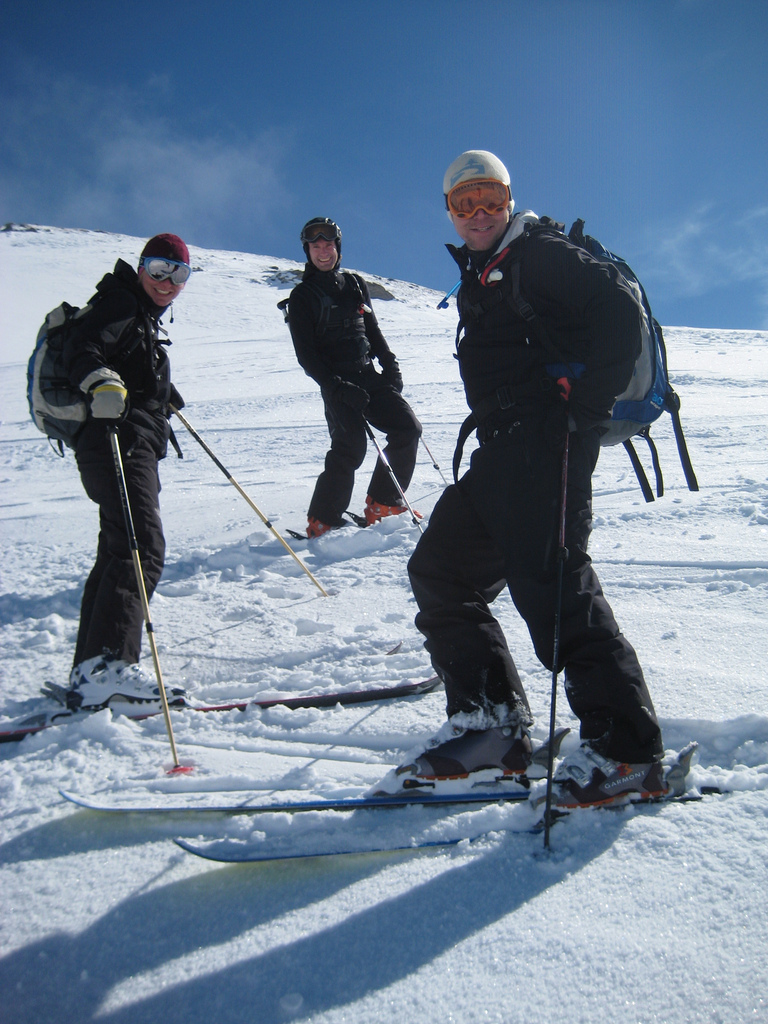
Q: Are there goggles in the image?
A: Yes, there are goggles.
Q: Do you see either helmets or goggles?
A: Yes, there are goggles.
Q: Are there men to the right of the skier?
A: Yes, there is a man to the right of the skier.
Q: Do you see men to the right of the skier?
A: Yes, there is a man to the right of the skier.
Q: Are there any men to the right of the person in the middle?
A: Yes, there is a man to the right of the skier.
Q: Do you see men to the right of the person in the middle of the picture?
A: Yes, there is a man to the right of the skier.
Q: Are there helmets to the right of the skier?
A: No, there is a man to the right of the skier.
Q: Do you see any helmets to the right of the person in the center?
A: No, there is a man to the right of the skier.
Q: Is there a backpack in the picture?
A: Yes, there is a backpack.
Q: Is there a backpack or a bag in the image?
A: Yes, there is a backpack.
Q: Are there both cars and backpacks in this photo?
A: No, there is a backpack but no cars.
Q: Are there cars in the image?
A: No, there are no cars.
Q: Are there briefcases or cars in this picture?
A: No, there are no cars or briefcases.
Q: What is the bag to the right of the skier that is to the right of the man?
A: The bag is a backpack.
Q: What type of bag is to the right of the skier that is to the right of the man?
A: The bag is a backpack.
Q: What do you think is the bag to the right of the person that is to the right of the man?
A: The bag is a backpack.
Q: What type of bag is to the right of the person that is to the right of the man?
A: The bag is a backpack.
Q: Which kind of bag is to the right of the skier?
A: The bag is a backpack.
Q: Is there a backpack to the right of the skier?
A: Yes, there is a backpack to the right of the skier.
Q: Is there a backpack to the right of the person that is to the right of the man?
A: Yes, there is a backpack to the right of the skier.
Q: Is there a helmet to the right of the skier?
A: No, there is a backpack to the right of the skier.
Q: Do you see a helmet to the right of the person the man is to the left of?
A: No, there is a backpack to the right of the skier.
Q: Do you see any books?
A: No, there are no books.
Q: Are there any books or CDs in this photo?
A: No, there are no books or cds.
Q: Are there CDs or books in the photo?
A: No, there are no books or cds.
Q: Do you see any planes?
A: No, there are no planes.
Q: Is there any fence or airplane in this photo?
A: No, there are no airplanes or fences.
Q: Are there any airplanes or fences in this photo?
A: No, there are no airplanes or fences.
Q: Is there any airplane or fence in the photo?
A: No, there are no airplanes or fences.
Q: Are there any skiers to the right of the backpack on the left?
A: Yes, there is a skier to the right of the backpack.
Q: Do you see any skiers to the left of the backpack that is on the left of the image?
A: No, the skier is to the right of the backpack.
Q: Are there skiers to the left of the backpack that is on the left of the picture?
A: No, the skier is to the right of the backpack.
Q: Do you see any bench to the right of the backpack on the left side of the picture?
A: No, there is a skier to the right of the backpack.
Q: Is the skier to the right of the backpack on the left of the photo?
A: Yes, the skier is to the right of the backpack.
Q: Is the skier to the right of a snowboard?
A: No, the skier is to the right of the backpack.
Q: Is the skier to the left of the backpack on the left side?
A: No, the skier is to the right of the backpack.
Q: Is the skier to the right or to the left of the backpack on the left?
A: The skier is to the right of the backpack.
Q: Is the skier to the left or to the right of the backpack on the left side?
A: The skier is to the right of the backpack.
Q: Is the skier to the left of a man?
A: Yes, the skier is to the left of a man.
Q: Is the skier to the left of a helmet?
A: No, the skier is to the left of a man.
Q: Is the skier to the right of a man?
A: No, the skier is to the left of a man.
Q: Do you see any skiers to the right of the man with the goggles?
A: Yes, there is a skier to the right of the man.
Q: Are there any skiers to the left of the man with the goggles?
A: No, the skier is to the right of the man.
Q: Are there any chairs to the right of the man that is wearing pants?
A: No, there is a skier to the right of the man.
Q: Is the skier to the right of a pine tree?
A: No, the skier is to the right of a man.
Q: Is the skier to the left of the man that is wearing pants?
A: No, the skier is to the right of the man.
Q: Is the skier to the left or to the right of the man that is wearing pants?
A: The skier is to the right of the man.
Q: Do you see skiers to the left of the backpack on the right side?
A: Yes, there is a skier to the left of the backpack.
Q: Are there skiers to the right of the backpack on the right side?
A: No, the skier is to the left of the backpack.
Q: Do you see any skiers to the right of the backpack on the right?
A: No, the skier is to the left of the backpack.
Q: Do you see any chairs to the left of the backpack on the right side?
A: No, there is a skier to the left of the backpack.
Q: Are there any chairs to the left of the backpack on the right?
A: No, there is a skier to the left of the backpack.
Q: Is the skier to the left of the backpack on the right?
A: Yes, the skier is to the left of the backpack.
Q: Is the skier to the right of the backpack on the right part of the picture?
A: No, the skier is to the left of the backpack.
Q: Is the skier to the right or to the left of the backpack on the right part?
A: The skier is to the left of the backpack.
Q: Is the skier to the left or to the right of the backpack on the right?
A: The skier is to the left of the backpack.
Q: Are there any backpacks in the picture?
A: Yes, there is a backpack.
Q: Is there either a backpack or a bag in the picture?
A: Yes, there is a backpack.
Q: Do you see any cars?
A: No, there are no cars.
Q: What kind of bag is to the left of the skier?
A: The bag is a backpack.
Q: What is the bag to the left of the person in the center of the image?
A: The bag is a backpack.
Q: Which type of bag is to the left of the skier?
A: The bag is a backpack.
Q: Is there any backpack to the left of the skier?
A: Yes, there is a backpack to the left of the skier.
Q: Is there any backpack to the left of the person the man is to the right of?
A: Yes, there is a backpack to the left of the skier.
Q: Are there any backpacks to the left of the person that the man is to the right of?
A: Yes, there is a backpack to the left of the skier.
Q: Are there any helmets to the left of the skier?
A: No, there is a backpack to the left of the skier.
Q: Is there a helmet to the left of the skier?
A: No, there is a backpack to the left of the skier.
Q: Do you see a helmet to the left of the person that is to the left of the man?
A: No, there is a backpack to the left of the skier.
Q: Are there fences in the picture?
A: No, there are no fences.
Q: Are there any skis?
A: Yes, there are skis.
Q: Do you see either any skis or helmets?
A: Yes, there are skis.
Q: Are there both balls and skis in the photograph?
A: No, there are skis but no balls.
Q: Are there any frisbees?
A: No, there are no frisbees.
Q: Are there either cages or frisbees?
A: No, there are no frisbees or cages.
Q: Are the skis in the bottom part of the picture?
A: Yes, the skis are in the bottom of the image.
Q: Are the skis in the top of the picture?
A: No, the skis are in the bottom of the image.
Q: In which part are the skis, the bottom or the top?
A: The skis are in the bottom of the image.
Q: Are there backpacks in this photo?
A: Yes, there is a backpack.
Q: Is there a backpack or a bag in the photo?
A: Yes, there is a backpack.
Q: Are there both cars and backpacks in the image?
A: No, there is a backpack but no cars.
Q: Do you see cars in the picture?
A: No, there are no cars.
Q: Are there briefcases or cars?
A: No, there are no cars or briefcases.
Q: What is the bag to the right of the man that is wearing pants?
A: The bag is a backpack.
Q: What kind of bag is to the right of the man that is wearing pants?
A: The bag is a backpack.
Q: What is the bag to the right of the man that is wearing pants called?
A: The bag is a backpack.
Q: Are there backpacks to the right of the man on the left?
A: Yes, there is a backpack to the right of the man.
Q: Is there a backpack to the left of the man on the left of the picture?
A: No, the backpack is to the right of the man.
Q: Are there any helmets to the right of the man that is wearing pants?
A: No, there is a backpack to the right of the man.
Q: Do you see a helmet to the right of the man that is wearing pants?
A: No, there is a backpack to the right of the man.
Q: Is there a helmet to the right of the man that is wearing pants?
A: No, there is a backpack to the right of the man.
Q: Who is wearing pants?
A: The man is wearing pants.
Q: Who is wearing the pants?
A: The man is wearing pants.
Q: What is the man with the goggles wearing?
A: The man is wearing pants.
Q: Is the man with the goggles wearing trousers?
A: Yes, the man is wearing trousers.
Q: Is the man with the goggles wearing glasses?
A: No, the man is wearing trousers.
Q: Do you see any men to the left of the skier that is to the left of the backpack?
A: Yes, there is a man to the left of the skier.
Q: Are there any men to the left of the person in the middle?
A: Yes, there is a man to the left of the skier.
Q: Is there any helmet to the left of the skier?
A: No, there is a man to the left of the skier.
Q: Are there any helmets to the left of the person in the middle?
A: No, there is a man to the left of the skier.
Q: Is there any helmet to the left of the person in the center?
A: No, there is a man to the left of the skier.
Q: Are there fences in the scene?
A: No, there are no fences.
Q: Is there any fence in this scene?
A: No, there are no fences.